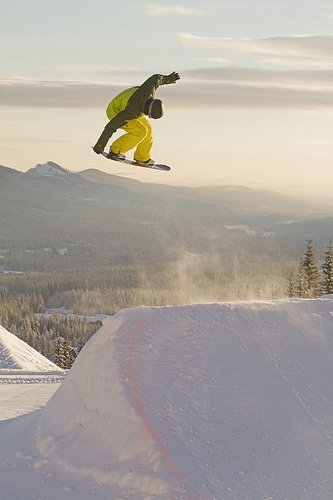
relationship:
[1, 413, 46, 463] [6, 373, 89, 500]
snow on ground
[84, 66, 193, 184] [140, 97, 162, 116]
snowboarder wearing hat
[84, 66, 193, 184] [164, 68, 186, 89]
snowboarder wearing gloves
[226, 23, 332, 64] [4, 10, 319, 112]
clouds in sky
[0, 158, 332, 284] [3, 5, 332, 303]
hill in background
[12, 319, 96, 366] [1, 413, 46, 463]
trees behind snow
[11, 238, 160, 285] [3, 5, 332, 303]
hill in background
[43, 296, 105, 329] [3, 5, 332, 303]
water in background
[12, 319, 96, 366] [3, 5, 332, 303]
trees in background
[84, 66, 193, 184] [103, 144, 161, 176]
snowboarder has feet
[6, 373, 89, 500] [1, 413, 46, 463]
ground has snow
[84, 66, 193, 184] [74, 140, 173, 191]
snowboarder holding board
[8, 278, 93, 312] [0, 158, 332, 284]
forest below hill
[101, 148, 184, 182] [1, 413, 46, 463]
snowboard above snow